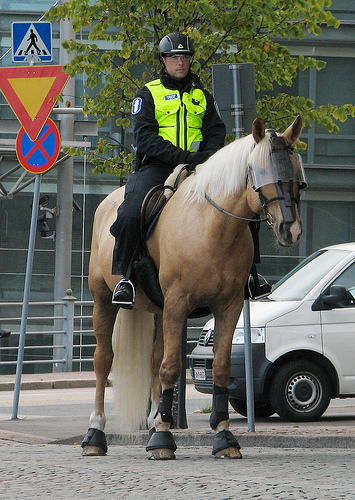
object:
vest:
[141, 75, 209, 169]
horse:
[72, 108, 314, 463]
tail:
[111, 303, 157, 440]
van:
[186, 234, 355, 427]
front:
[164, 130, 318, 488]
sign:
[5, 17, 57, 69]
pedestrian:
[11, 23, 53, 61]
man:
[106, 21, 272, 321]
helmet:
[155, 30, 198, 58]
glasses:
[163, 53, 196, 64]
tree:
[42, 0, 355, 435]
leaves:
[324, 109, 334, 126]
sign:
[0, 57, 81, 145]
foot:
[206, 421, 244, 463]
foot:
[143, 424, 178, 466]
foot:
[77, 418, 108, 462]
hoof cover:
[208, 426, 242, 455]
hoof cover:
[144, 426, 180, 452]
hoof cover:
[79, 425, 109, 450]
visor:
[245, 148, 312, 191]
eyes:
[256, 162, 269, 181]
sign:
[9, 108, 66, 181]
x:
[19, 122, 57, 170]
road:
[0, 411, 355, 500]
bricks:
[2, 446, 347, 498]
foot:
[108, 270, 139, 314]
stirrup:
[111, 276, 137, 307]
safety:
[157, 48, 194, 68]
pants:
[107, 162, 270, 295]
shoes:
[110, 279, 140, 314]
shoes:
[243, 269, 279, 309]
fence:
[0, 246, 355, 380]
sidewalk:
[0, 364, 109, 392]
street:
[0, 372, 355, 424]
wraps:
[258, 191, 305, 246]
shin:
[273, 214, 305, 247]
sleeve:
[127, 88, 158, 162]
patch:
[129, 94, 144, 118]